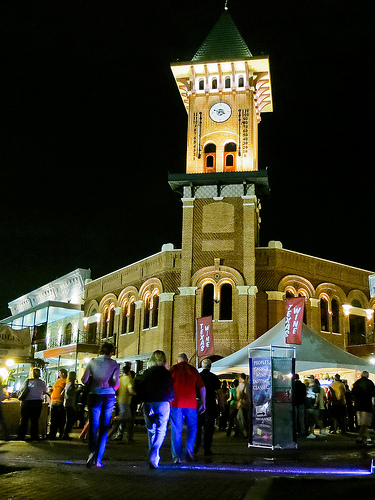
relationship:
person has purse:
[80, 336, 122, 475] [79, 375, 93, 400]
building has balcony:
[0, 3, 373, 378] [165, 167, 271, 196]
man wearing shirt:
[167, 353, 206, 467] [168, 364, 203, 410]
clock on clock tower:
[208, 100, 233, 126] [166, 3, 261, 248]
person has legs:
[80, 336, 122, 475] [97, 397, 115, 465]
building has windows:
[0, 3, 373, 378] [199, 282, 233, 323]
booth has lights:
[1, 321, 42, 442] [3, 358, 15, 368]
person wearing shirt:
[80, 336, 122, 475] [82, 357, 123, 394]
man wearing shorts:
[351, 368, 373, 446] [353, 408, 371, 428]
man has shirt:
[167, 353, 206, 467] [168, 364, 203, 410]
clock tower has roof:
[166, 3, 261, 248] [185, 10, 257, 59]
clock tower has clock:
[166, 3, 261, 248] [208, 100, 233, 126]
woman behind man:
[133, 351, 173, 470] [167, 353, 206, 467]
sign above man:
[195, 317, 213, 362] [167, 353, 206, 467]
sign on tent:
[279, 295, 305, 347] [198, 310, 374, 383]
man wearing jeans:
[167, 353, 206, 467] [169, 405, 198, 456]